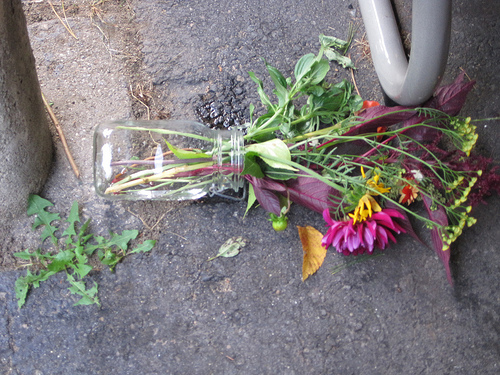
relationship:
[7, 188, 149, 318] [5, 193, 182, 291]
dandelion in crack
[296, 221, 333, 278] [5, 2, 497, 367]
leaf on concrete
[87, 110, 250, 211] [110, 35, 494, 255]
jar with flowers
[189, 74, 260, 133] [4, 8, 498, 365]
water on ground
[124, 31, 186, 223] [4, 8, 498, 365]
grass on ground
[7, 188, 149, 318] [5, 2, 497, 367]
dandelion growing through pavement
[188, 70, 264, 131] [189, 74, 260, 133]
spot shows water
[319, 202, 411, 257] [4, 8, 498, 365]
flower on ground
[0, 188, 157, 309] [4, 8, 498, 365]
dandelion on ground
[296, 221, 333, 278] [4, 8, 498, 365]
leaf on ground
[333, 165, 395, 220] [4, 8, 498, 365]
flowers on ground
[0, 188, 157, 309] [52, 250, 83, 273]
dandelion has stem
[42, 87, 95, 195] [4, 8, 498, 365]
stick on ground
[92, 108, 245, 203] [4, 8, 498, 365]
vase on ground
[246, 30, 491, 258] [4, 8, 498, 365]
bunch on ground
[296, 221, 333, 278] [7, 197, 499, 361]
leaf on side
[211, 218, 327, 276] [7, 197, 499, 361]
stuff on side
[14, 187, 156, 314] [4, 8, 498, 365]
weed out of ground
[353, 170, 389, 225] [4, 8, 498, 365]
flower on ground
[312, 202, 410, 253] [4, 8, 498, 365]
petals on ground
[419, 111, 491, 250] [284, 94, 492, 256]
flowers in bouquet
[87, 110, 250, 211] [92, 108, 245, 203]
jar used as vase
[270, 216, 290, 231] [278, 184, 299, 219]
berry on stem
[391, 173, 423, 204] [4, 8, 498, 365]
flower on ground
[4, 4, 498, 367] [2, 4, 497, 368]
asphalt has surface